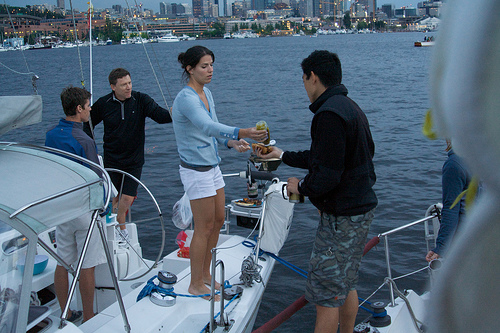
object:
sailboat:
[0, 84, 308, 331]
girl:
[159, 42, 265, 302]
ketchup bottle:
[253, 119, 271, 149]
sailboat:
[250, 0, 483, 329]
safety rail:
[253, 200, 453, 330]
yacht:
[154, 29, 184, 44]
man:
[32, 79, 114, 329]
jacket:
[40, 118, 108, 161]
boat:
[258, 4, 500, 333]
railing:
[238, 199, 462, 330]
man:
[77, 59, 172, 248]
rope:
[231, 241, 392, 331]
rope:
[123, 269, 243, 302]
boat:
[1, 16, 302, 329]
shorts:
[302, 207, 376, 308]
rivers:
[15, 48, 447, 220]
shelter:
[0, 118, 133, 304]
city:
[16, 7, 405, 40]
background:
[0, 0, 449, 51]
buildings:
[3, 2, 437, 40]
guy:
[263, 49, 378, 333]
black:
[89, 91, 176, 177]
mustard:
[249, 120, 275, 170]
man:
[276, 39, 402, 329]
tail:
[169, 47, 189, 70]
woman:
[160, 30, 275, 300]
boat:
[413, 32, 442, 47]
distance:
[377, 20, 456, 141]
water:
[0, 38, 477, 257]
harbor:
[5, 192, 481, 330]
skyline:
[6, 2, 481, 52]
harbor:
[27, 13, 457, 48]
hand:
[238, 124, 267, 145]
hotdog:
[245, 136, 288, 163]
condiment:
[253, 111, 279, 141]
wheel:
[77, 155, 197, 300]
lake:
[0, 42, 426, 176]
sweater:
[283, 84, 381, 213]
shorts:
[53, 211, 105, 267]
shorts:
[97, 145, 146, 197]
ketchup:
[253, 124, 269, 144]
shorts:
[177, 162, 226, 203]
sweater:
[172, 82, 239, 169]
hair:
[175, 45, 213, 75]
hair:
[301, 47, 342, 88]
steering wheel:
[99, 167, 168, 288]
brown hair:
[109, 68, 128, 84]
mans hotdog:
[237, 53, 363, 212]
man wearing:
[38, 88, 109, 287]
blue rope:
[266, 253, 309, 278]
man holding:
[281, 49, 377, 333]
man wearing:
[284, 45, 378, 333]